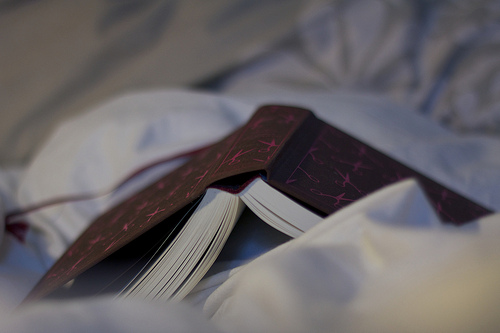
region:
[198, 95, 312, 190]
the spine of a book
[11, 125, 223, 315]
the front cover of a book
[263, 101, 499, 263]
the back cover of a book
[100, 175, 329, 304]
the pages of a book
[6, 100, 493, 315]
a book on the bed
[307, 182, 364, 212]
pink scissors on the book cover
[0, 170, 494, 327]
a white sheet in front of the book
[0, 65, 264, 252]
a pillow behind the book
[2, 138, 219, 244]
a red bookmark for the book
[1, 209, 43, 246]
the end of a bookmark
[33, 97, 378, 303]
a book placed down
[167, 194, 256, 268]
pages of the book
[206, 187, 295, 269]
a gap in between book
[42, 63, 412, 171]
a white clothe in bed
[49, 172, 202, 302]
top of the book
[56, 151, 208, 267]
a brown cover of the book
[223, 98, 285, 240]
middle area of the book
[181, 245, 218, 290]
a small space between pages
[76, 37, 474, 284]
a big book placed in clothes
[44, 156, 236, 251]
a small design on book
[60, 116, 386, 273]
dark red cover on book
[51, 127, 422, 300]
red book on bed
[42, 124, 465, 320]
book on bed is open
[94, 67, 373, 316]
bed has white sheet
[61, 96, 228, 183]
dark red bookmark on bed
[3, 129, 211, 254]
red satin bookmark on bed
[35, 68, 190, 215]
white bedsheet behind book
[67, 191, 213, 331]
dark colored end pages on book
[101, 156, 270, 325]
book is open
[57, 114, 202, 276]
pink writing on book cover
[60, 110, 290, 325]
a book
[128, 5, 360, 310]
a book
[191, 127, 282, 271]
a book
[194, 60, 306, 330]
a book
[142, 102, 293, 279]
a book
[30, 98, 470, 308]
An open book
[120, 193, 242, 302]
White pages of a book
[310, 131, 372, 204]
Pink patterns on the book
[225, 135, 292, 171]
Pink scissors drawn on the book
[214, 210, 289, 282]
A gap between the pages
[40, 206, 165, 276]
A book cover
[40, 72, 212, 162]
White cloth behind the book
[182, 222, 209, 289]
Small opening between the pages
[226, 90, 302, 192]
The book's spine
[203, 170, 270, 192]
Book spine gap